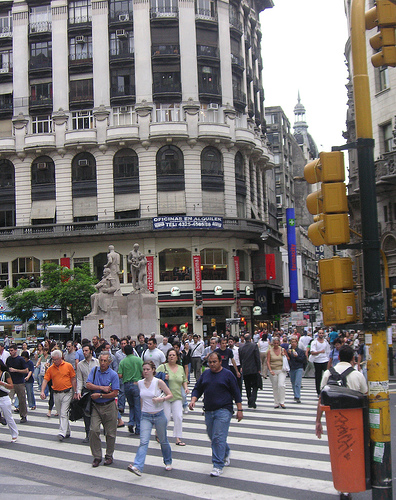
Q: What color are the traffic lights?
A: Yellow.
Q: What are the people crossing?
A: A street.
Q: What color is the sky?
A: White.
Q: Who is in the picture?
A: Men and women.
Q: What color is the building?
A: Stone.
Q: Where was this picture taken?
A: A city street.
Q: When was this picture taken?
A: Daytime.